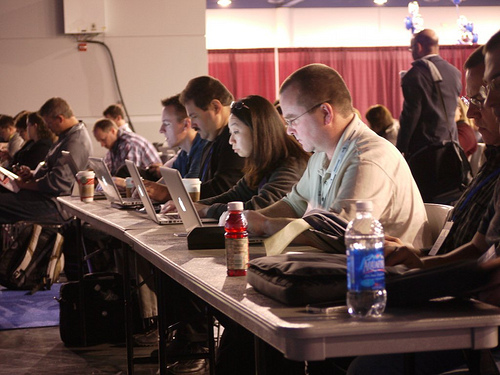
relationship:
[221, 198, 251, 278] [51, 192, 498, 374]
bottle on top of table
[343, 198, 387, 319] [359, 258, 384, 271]
bottle says aquafina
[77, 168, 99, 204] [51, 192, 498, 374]
cup on top of table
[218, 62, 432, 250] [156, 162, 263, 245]
person working on laptop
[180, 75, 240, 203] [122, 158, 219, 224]
man working on laptop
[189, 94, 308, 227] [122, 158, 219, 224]
woman working on laptop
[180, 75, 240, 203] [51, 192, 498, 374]
man sitting at table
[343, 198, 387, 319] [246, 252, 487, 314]
bottle kept beside bag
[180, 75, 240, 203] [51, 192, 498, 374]
man sitting at a table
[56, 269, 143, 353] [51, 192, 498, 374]
bag lying under table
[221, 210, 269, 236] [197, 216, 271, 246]
hand hovering over keyboard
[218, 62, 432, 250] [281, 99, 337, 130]
person wearing glasses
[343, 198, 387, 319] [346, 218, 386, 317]
bottle of water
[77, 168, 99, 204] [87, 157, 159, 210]
cup standing near laptop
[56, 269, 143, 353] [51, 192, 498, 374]
bag lying beneath table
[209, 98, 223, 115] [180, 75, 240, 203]
left ear of man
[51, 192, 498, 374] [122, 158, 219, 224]
table standing beneath laptop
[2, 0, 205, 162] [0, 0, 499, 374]
wall standing in room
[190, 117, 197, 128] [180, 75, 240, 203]
nose of man